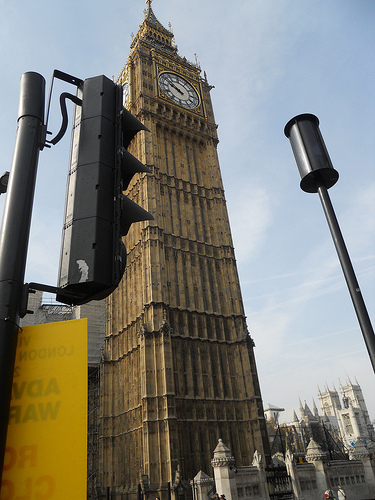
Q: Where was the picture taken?
A: London.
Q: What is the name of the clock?
A: Big Ben.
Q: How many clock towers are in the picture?
A: 1.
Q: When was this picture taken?
A: 9:50.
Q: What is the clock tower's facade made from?
A: Stone.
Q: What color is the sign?
A: Yellow.